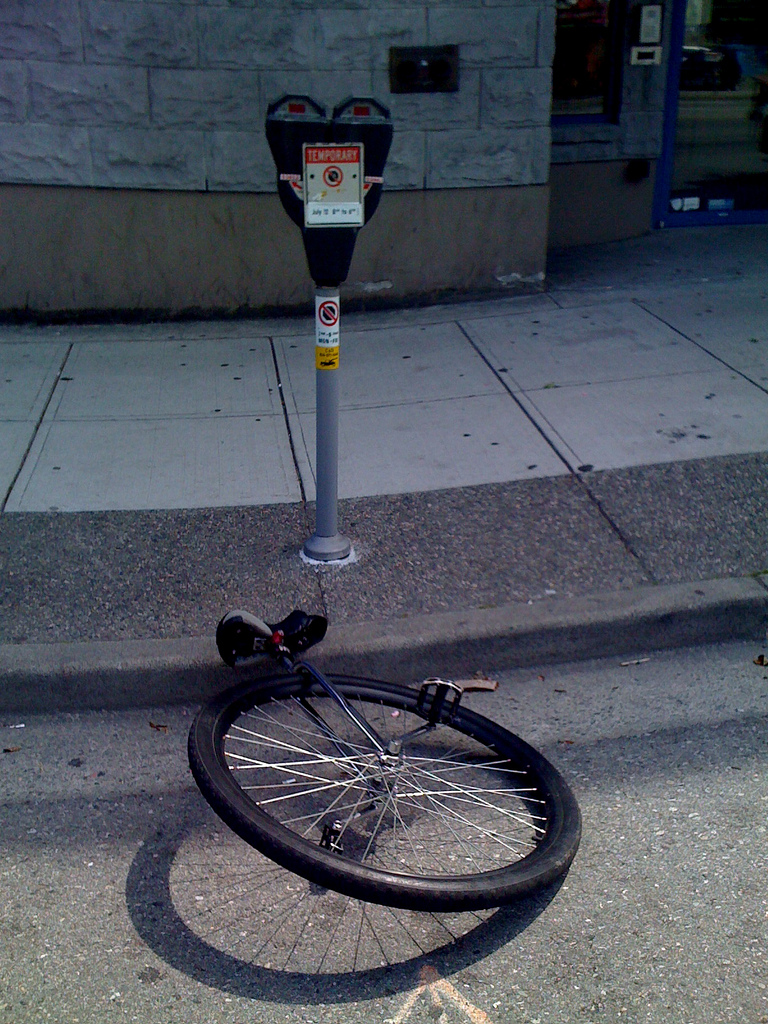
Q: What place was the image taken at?
A: It was taken at the sidewalk.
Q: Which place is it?
A: It is a sidewalk.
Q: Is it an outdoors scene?
A: Yes, it is outdoors.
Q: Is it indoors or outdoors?
A: It is outdoors.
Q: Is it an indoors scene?
A: No, it is outdoors.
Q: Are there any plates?
A: Yes, there is a plate.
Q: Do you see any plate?
A: Yes, there is a plate.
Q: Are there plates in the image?
A: Yes, there is a plate.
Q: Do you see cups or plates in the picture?
A: Yes, there is a plate.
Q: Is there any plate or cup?
A: Yes, there is a plate.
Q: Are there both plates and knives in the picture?
A: No, there is a plate but no knives.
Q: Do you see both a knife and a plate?
A: No, there is a plate but no knives.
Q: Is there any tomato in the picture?
A: No, there are no tomatoes.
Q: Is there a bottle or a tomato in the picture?
A: No, there are no tomatoes or bottles.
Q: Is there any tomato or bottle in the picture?
A: No, there are no tomatoes or bottles.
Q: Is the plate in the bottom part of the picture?
A: No, the plate is in the top of the image.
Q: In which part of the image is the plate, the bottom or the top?
A: The plate is in the top of the image.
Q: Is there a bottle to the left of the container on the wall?
A: No, there is a plate to the left of the box.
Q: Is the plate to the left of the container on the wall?
A: Yes, the plate is to the left of the box.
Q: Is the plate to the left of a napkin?
A: No, the plate is to the left of the box.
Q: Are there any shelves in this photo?
A: No, there are no shelves.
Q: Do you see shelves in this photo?
A: No, there are no shelves.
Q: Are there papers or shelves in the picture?
A: No, there are no shelves or papers.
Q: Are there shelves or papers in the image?
A: No, there are no shelves or papers.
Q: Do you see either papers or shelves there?
A: No, there are no shelves or papers.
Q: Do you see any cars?
A: No, there are no cars.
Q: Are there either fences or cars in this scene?
A: No, there are no cars or fences.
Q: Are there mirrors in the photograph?
A: No, there are no mirrors.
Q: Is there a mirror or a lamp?
A: No, there are no mirrors or lamps.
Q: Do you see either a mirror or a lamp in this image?
A: No, there are no mirrors or lamps.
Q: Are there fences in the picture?
A: No, there are no fences.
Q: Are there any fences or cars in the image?
A: No, there are no fences or cars.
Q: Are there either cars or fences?
A: No, there are no fences or cars.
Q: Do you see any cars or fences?
A: No, there are no fences or cars.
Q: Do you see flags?
A: No, there are no flags.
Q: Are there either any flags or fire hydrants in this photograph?
A: No, there are no flags or fire hydrants.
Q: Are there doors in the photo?
A: Yes, there is a door.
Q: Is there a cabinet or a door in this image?
A: Yes, there is a door.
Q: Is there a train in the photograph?
A: No, there are no trains.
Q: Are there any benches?
A: No, there are no benches.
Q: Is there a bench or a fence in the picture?
A: No, there are no benches or fences.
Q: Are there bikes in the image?
A: Yes, there is a bike.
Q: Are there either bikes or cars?
A: Yes, there is a bike.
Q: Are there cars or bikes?
A: Yes, there is a bike.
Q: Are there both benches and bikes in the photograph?
A: No, there is a bike but no benches.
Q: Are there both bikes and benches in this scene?
A: No, there is a bike but no benches.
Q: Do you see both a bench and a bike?
A: No, there is a bike but no benches.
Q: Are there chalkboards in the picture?
A: No, there are no chalkboards.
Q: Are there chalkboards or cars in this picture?
A: No, there are no chalkboards or cars.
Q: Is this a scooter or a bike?
A: This is a bike.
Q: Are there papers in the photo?
A: No, there are no papers.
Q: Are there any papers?
A: No, there are no papers.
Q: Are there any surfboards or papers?
A: No, there are no papers or surfboards.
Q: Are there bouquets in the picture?
A: No, there are no bouquets.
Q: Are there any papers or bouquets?
A: No, there are no bouquets or papers.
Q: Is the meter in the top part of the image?
A: Yes, the meter is in the top of the image.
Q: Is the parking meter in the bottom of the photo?
A: No, the parking meter is in the top of the image.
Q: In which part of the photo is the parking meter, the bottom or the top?
A: The parking meter is in the top of the image.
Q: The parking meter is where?
A: The parking meter is on the sidewalk.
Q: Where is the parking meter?
A: The parking meter is on the sidewalk.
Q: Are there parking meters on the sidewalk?
A: Yes, there is a parking meter on the sidewalk.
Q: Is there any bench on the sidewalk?
A: No, there is a parking meter on the sidewalk.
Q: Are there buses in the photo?
A: No, there are no buses.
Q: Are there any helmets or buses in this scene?
A: No, there are no buses or helmets.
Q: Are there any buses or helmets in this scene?
A: No, there are no buses or helmets.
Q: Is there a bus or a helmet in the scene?
A: No, there are no buses or helmets.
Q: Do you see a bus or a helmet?
A: No, there are no buses or helmets.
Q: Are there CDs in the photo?
A: No, there are no cds.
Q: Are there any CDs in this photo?
A: No, there are no cds.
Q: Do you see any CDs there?
A: No, there are no cds.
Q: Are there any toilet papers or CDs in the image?
A: No, there are no CDs or toilet papers.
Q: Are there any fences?
A: No, there are no fences.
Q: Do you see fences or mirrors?
A: No, there are no fences or mirrors.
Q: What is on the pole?
A: The sticker is on the pole.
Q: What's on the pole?
A: The sticker is on the pole.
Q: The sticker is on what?
A: The sticker is on the pole.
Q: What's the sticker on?
A: The sticker is on the pole.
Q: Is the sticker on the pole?
A: Yes, the sticker is on the pole.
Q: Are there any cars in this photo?
A: No, there are no cars.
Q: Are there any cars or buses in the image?
A: No, there are no cars or buses.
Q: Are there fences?
A: No, there are no fences.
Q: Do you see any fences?
A: No, there are no fences.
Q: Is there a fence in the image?
A: No, there are no fences.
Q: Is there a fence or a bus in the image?
A: No, there are no fences or buses.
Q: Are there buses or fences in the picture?
A: No, there are no fences or buses.